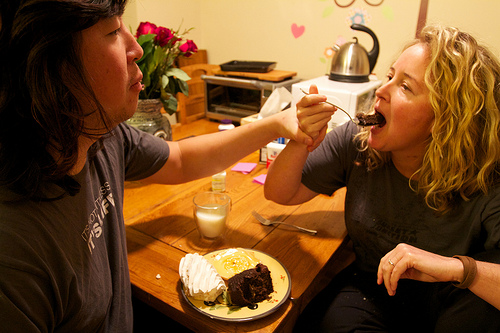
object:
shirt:
[0, 123, 170, 333]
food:
[178, 250, 274, 309]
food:
[355, 113, 384, 126]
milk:
[195, 211, 227, 239]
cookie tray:
[219, 60, 277, 73]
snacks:
[178, 246, 274, 309]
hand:
[376, 242, 456, 297]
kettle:
[329, 23, 381, 83]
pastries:
[222, 262, 283, 312]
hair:
[0, 0, 132, 205]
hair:
[351, 24, 499, 216]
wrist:
[286, 132, 321, 144]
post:
[232, 163, 257, 173]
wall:
[206, 0, 483, 64]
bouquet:
[128, 17, 198, 115]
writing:
[81, 180, 115, 256]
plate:
[178, 247, 291, 323]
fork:
[299, 87, 380, 126]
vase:
[123, 98, 171, 143]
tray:
[215, 96, 259, 115]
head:
[353, 24, 500, 217]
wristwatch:
[450, 255, 477, 290]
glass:
[192, 192, 231, 244]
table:
[123, 117, 346, 332]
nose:
[375, 79, 394, 103]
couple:
[0, 0, 500, 333]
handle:
[351, 23, 380, 55]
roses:
[129, 12, 199, 115]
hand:
[294, 83, 338, 140]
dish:
[179, 248, 292, 322]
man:
[0, 0, 327, 333]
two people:
[0, 0, 497, 333]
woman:
[264, 26, 500, 333]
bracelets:
[451, 254, 476, 290]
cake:
[179, 249, 274, 306]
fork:
[251, 211, 318, 235]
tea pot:
[328, 23, 381, 83]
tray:
[218, 60, 277, 73]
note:
[231, 162, 258, 173]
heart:
[291, 22, 306, 39]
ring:
[388, 260, 396, 267]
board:
[216, 70, 296, 81]